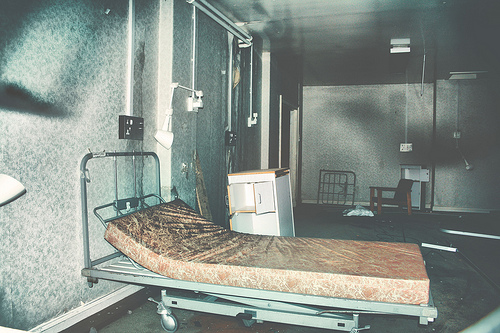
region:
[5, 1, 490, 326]
abandoned room with furniture and fixtures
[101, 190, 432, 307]
curled mattress with black dirt on one end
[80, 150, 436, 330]
mattress on folding metal support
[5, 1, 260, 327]
wallpaper with small floral print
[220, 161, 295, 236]
slanted cabinet with open doors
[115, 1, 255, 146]
poles, lamp and covered wiring on wall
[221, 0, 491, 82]
shiny surface of ceiling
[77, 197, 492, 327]
dark and dirty floor with scratch lines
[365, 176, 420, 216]
wooden chair with dark cushions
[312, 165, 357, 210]
metal frame against faded wall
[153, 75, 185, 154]
white lamp on the wall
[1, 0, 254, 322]
wall paper on the wall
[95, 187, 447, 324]
mattress on the bed frame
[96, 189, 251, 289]
top of the mattress is propped up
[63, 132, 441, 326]
metal bed frame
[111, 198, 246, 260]
black marks on the top of the mattress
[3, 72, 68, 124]
black mark on the wall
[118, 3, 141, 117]
white pole running along the wall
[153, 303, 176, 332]
wheel on the bottom of the bed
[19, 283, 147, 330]
white trim on the bottom of the wall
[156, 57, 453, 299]
room is in a hospital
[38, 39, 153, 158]
walls aare green in color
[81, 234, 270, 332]
bed is metallic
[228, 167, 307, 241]
fridge is white in color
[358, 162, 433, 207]
seat is wooden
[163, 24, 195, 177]
light globes are white in color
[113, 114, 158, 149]
socket is black in color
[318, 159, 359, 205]
a metalic table folded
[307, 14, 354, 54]
the ceiling is green in color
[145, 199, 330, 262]
the matres is multicolored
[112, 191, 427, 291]
the bed is empty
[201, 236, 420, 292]
the bed is empty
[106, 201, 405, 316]
the bed is empty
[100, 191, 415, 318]
the bed is empty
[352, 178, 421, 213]
the chair is empty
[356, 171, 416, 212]
the chair is empty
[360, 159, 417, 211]
the chair is empty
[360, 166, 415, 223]
the chair is empty